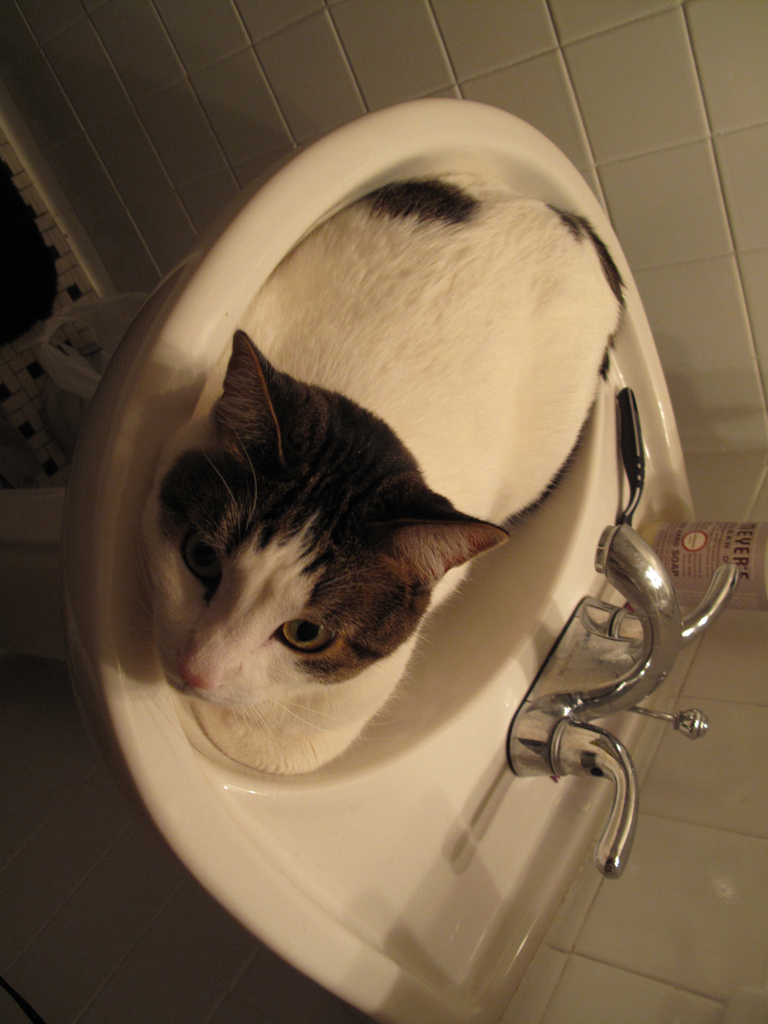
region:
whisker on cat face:
[197, 400, 266, 537]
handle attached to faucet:
[559, 714, 645, 878]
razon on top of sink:
[616, 384, 664, 540]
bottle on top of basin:
[643, 493, 764, 608]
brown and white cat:
[128, 178, 633, 800]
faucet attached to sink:
[510, 513, 742, 884]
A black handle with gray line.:
[617, 386, 645, 486]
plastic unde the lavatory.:
[40, 289, 143, 393]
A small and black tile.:
[65, 284, 82, 299]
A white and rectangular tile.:
[130, 81, 229, 188]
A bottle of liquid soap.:
[641, 517, 766, 609]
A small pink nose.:
[173, 661, 209, 687]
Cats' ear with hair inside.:
[403, 517, 508, 580]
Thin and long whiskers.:
[262, 691, 403, 742]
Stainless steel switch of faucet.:
[547, 715, 641, 879]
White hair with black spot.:
[368, 173, 507, 247]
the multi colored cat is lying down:
[137, 162, 628, 774]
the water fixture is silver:
[505, 517, 739, 879]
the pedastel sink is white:
[2, 95, 700, 1017]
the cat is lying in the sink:
[4, 98, 697, 1021]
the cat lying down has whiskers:
[133, 168, 628, 778]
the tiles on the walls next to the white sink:
[2, 1, 763, 1020]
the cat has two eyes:
[126, 170, 626, 776]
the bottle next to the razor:
[614, 387, 766, 611]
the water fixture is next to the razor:
[505, 385, 738, 882]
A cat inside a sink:
[74, 51, 655, 991]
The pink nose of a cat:
[169, 616, 241, 699]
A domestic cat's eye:
[266, 599, 348, 662]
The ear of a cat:
[210, 321, 305, 491]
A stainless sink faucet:
[543, 505, 747, 938]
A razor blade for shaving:
[607, 359, 653, 540]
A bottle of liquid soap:
[645, 510, 764, 602]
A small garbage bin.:
[38, 215, 182, 507]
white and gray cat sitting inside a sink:
[145, 171, 609, 775]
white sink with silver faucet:
[43, 96, 753, 1014]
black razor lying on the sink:
[603, 385, 650, 539]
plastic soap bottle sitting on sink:
[641, 518, 766, 602]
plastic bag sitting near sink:
[40, 292, 148, 448]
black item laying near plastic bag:
[0, 161, 62, 348]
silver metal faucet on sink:
[569, 517, 685, 734]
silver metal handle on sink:
[555, 721, 646, 872]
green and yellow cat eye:
[271, 609, 349, 652]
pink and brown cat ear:
[384, 479, 509, 581]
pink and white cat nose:
[170, 643, 225, 692]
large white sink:
[63, 97, 709, 1022]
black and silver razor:
[615, 382, 650, 533]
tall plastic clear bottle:
[627, 520, 767, 613]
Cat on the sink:
[53, 91, 748, 987]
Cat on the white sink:
[59, 93, 703, 1022]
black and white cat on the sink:
[54, 90, 710, 1012]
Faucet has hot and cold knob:
[500, 514, 746, 881]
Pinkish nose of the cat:
[171, 636, 233, 695]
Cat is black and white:
[134, 167, 633, 780]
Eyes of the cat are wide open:
[177, 518, 345, 658]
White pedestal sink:
[4, 93, 759, 1015]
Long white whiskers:
[87, 506, 402, 766]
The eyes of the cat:
[193, 579, 354, 667]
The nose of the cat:
[179, 646, 232, 704]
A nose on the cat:
[177, 641, 240, 688]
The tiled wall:
[478, 581, 766, 1022]